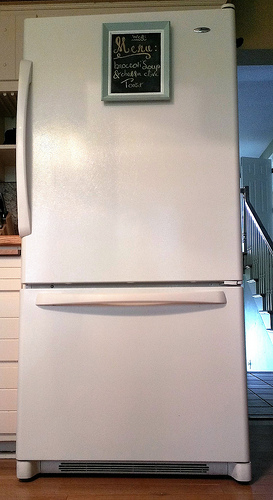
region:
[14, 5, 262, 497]
The refrigerator in the kitchen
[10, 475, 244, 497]
The floor is made of wood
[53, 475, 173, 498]
The color of the floor is brown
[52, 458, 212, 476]
The vent at the bottom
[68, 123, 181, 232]
The color of the refrigerator is white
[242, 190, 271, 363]
The stairs in the other room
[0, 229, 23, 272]
The kitchen counter is made of wood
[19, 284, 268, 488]
The bottom half of the fridge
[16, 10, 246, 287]
The top half of the fridge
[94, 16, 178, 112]
A menu magnet on the fridge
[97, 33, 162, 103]
chalk writing on board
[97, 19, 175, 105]
green frame on board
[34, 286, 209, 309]
white handle on freezer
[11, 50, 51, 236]
white handle on fridge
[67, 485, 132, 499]
brown wood on floor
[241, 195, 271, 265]
railing on steps outside kitchen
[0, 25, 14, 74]
white cupboard near fridge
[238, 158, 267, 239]
white door outside kitchen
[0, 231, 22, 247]
brown counter near fridge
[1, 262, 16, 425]
white drawers near fridge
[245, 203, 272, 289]
the stair are made of metal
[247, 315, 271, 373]
the light is reflected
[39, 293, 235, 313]
the handle is white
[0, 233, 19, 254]
the top of the table is wooden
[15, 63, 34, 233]
the handle is white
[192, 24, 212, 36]
the end is silver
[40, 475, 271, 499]
the floor is made of wood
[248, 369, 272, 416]
the floor is tiled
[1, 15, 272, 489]
the focus of the photo is the fridge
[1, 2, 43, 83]
the shelf are mounted up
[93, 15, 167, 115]
green frame on sign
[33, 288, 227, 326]
white handle on freezer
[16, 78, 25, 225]
white handle on fridge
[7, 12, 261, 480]
white fridge and freezer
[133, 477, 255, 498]
floor is dark brown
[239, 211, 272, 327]
white stairs outside kitchen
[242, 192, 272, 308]
brown rail near stairs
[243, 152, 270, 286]
white door by stairs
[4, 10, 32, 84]
white cabinets near fridge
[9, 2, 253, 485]
A fridge with a small chalk board on the top door